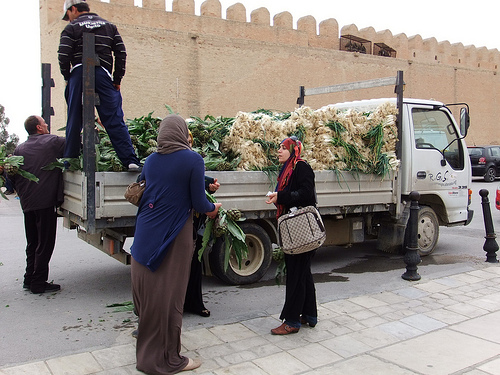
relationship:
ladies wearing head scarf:
[266, 136, 314, 338] [280, 138, 308, 193]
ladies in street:
[266, 136, 314, 338] [221, 278, 499, 343]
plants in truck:
[203, 112, 387, 168] [65, 90, 481, 276]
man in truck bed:
[52, 0, 139, 172] [68, 105, 234, 217]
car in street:
[470, 146, 499, 187] [471, 175, 499, 189]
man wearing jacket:
[10, 112, 70, 300] [16, 135, 63, 209]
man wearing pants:
[10, 112, 70, 300] [19, 207, 59, 286]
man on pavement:
[10, 112, 70, 300] [12, 289, 106, 330]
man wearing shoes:
[10, 112, 70, 300] [20, 280, 67, 296]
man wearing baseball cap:
[52, 0, 139, 172] [59, 0, 91, 22]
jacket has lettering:
[56, 14, 131, 88] [74, 18, 115, 34]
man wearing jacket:
[52, 0, 139, 172] [56, 14, 131, 88]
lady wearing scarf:
[131, 112, 211, 373] [154, 114, 196, 156]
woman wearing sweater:
[131, 112, 211, 373] [130, 150, 212, 271]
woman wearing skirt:
[131, 112, 211, 373] [134, 217, 190, 372]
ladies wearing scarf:
[266, 136, 314, 338] [280, 138, 308, 193]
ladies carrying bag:
[266, 136, 314, 338] [275, 203, 327, 254]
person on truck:
[52, 0, 139, 172] [65, 90, 481, 276]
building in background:
[120, 2, 347, 102] [40, 0, 499, 106]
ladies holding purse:
[266, 136, 314, 338] [275, 203, 327, 254]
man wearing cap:
[52, 0, 139, 172] [59, 0, 91, 22]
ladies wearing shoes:
[266, 136, 314, 338] [269, 321, 300, 337]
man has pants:
[10, 112, 70, 300] [19, 207, 59, 286]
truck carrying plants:
[65, 90, 481, 276] [203, 112, 387, 168]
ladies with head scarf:
[266, 136, 314, 338] [276, 136, 308, 216]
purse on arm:
[275, 203, 327, 254] [264, 166, 318, 213]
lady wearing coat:
[131, 112, 211, 373] [130, 150, 212, 271]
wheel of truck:
[404, 209, 445, 258] [65, 90, 481, 276]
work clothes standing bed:
[52, 0, 139, 172] [60, 151, 143, 197]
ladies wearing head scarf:
[266, 136, 314, 338] [276, 136, 308, 216]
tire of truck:
[206, 218, 280, 283] [65, 90, 481, 276]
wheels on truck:
[206, 218, 280, 283] [65, 90, 481, 276]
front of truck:
[378, 100, 484, 270] [65, 90, 481, 276]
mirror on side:
[453, 100, 473, 141] [398, 87, 488, 228]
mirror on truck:
[453, 100, 473, 141] [65, 90, 481, 276]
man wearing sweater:
[52, 0, 139, 172] [56, 14, 131, 88]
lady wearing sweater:
[131, 112, 211, 373] [130, 150, 212, 271]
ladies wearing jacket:
[266, 136, 314, 338] [264, 166, 318, 213]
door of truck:
[398, 87, 488, 228] [65, 90, 481, 276]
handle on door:
[415, 171, 428, 181] [398, 87, 488, 228]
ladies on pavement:
[131, 110, 325, 367] [12, 262, 499, 375]